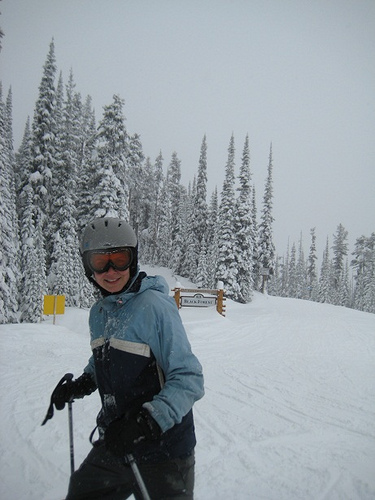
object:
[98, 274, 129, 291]
smile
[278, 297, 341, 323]
slope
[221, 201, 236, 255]
snow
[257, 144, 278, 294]
pine tree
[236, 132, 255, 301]
pine tree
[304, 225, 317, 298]
pine tree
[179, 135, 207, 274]
pine tree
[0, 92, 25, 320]
pine tree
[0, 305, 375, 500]
ground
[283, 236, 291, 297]
tree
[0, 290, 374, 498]
snow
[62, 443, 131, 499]
leg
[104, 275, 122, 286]
mouth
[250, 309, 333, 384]
pizza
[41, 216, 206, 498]
female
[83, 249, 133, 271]
goggles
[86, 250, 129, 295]
face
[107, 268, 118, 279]
nose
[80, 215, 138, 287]
helmet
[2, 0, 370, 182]
sky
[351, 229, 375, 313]
tree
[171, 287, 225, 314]
sign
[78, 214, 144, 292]
head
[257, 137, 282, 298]
pine tree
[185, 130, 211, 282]
pine tree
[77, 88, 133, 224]
pine tree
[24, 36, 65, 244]
pine tree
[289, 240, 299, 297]
pine trees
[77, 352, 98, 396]
arm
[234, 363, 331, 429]
tracks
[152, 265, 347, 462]
ski slope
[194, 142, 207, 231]
snow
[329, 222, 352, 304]
snow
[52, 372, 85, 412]
hand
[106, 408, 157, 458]
gloves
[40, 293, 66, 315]
sign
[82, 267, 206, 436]
jacket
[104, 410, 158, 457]
hand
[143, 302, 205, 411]
arm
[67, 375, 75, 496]
ski pole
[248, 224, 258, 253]
snow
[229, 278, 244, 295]
snow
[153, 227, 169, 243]
snow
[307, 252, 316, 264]
snow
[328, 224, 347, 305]
tree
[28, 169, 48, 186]
snow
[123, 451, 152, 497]
ski poles